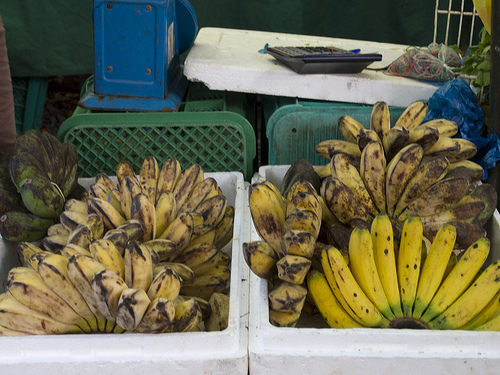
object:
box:
[78, 0, 200, 112]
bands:
[383, 38, 460, 82]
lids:
[184, 99, 223, 100]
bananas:
[0, 130, 80, 243]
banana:
[20, 176, 67, 218]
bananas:
[0, 101, 499, 332]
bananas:
[0, 131, 230, 341]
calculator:
[266, 43, 383, 71]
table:
[72, 98, 253, 126]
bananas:
[294, 139, 499, 330]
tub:
[227, 243, 499, 374]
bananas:
[297, 210, 499, 334]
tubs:
[0, 166, 499, 375]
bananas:
[0, 158, 232, 336]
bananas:
[305, 210, 499, 331]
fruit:
[240, 99, 498, 331]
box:
[245, 161, 499, 364]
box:
[180, 21, 482, 104]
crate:
[59, 92, 253, 184]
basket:
[56, 75, 256, 177]